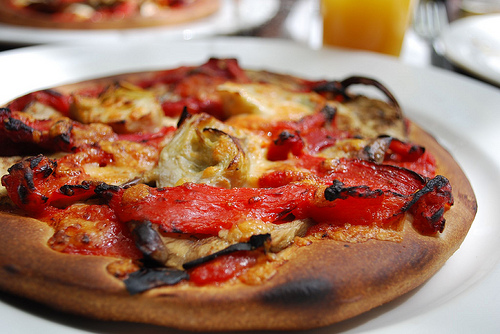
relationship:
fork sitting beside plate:
[410, 1, 447, 68] [444, 13, 500, 84]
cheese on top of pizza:
[90, 139, 154, 186] [3, 59, 471, 324]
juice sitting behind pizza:
[325, 0, 409, 46] [3, 59, 471, 324]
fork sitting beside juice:
[410, 1, 447, 68] [325, 0, 409, 46]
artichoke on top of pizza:
[157, 112, 260, 188] [3, 59, 471, 324]